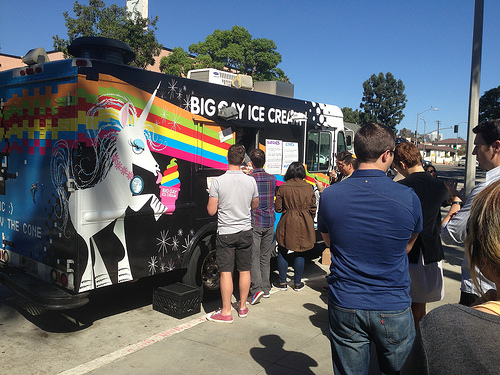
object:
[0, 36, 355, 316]
truck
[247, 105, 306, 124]
ice cream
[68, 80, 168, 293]
unicorn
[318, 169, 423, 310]
shirt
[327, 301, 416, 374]
jeans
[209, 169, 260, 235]
shirt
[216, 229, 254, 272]
shorts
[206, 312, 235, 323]
shoes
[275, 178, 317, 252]
coat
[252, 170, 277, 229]
shirt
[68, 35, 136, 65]
vent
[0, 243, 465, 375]
pavement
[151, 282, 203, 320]
crate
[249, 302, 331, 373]
shadow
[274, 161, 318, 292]
person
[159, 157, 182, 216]
ice cream cone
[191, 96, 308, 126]
letters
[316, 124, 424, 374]
person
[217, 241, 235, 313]
legs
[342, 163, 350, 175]
face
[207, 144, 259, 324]
people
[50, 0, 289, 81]
trees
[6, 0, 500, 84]
sky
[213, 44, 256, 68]
leaves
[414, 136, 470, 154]
roofs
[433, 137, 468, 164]
houses